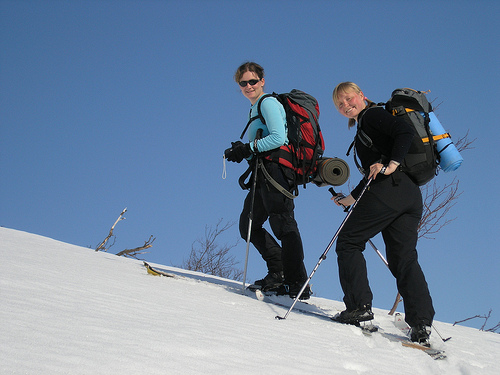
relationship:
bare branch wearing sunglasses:
[179, 215, 244, 281] [232, 71, 274, 95]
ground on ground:
[0, 228, 500, 375] [0, 226, 499, 373]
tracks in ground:
[332, 309, 489, 361] [0, 228, 500, 375]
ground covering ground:
[0, 228, 500, 375] [0, 226, 499, 373]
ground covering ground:
[0, 228, 500, 375] [5, 212, 195, 349]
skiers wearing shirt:
[223, 62, 310, 299] [246, 91, 288, 156]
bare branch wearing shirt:
[179, 215, 244, 281] [240, 86, 290, 162]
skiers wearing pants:
[223, 62, 310, 299] [242, 160, 310, 296]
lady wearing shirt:
[331, 80, 436, 345] [243, 94, 290, 153]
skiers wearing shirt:
[223, 62, 310, 299] [353, 105, 425, 190]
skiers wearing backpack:
[223, 62, 310, 299] [265, 87, 349, 185]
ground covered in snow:
[21, 263, 160, 335] [221, 326, 371, 365]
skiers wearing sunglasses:
[223, 62, 310, 299] [236, 77, 259, 87]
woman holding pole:
[319, 76, 434, 348] [273, 170, 386, 320]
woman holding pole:
[319, 76, 434, 348] [328, 182, 454, 346]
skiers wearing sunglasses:
[223, 62, 310, 299] [232, 76, 257, 89]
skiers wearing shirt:
[223, 62, 310, 299] [240, 95, 287, 170]